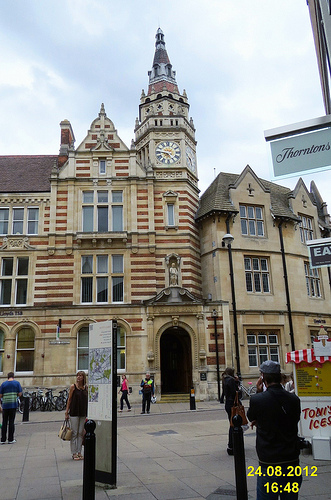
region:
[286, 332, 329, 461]
Red and white ice cream stand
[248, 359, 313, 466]
Man talking on cell phone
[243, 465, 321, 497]
Yellow time and date stamp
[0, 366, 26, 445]
Man wearing blue and green shirt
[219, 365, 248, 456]
Woman carry brown purse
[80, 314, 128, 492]
Map displayed on sidewalk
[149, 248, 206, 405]
Statue over arched doorway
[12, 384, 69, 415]
Bicycle parked near building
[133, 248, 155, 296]
Brown and tan bricks on building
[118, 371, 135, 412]
Women wearing a pink shirt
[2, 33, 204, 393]
a very tall striped building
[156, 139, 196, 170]
the two clocks on the bottom of the tower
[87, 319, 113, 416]
the sign giving directions around town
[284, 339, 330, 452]
a kiosk selling assorted ices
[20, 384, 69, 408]
a line of bikes outside the building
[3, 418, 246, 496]
part of the sidewalk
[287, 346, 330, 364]
the top of the kiosk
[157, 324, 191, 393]
the tall doorway for the building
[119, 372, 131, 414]
a woman walking down the street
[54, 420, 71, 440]
the purse the woman is holding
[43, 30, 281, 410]
old building with tall clock tower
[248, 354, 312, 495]
man talking on cell phone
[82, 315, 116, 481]
map with explanations for tourists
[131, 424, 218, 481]
large grey stones make up the street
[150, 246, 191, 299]
statue standing above an entrance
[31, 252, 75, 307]
red and beige stripes on the building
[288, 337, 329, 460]
cart selling ice cream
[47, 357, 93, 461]
woman with grey pants looks confused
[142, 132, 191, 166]
clock on the tower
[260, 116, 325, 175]
sign advertising Thornton's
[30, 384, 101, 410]
Bicycles parked on the sidewalk.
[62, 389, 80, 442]
a lady carrying a handbag.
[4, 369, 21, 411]
The shirt has stripes in the middle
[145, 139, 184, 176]
the building has a clock on top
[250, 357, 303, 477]
A man talking on a cell phone.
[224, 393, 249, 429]
The handbag is brown.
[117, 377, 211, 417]
People walking on the sidewalk.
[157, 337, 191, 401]
The door of the building.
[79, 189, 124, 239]
the building has windows.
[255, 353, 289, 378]
The man is wearing a hat.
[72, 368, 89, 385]
the head of a woman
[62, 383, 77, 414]
the arm of a woman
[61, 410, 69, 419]
the hand of a woman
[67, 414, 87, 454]
a pair of gray pants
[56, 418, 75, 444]
a tan bag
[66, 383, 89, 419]
a black tank top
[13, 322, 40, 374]
a window on the building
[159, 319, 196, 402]
a large doorway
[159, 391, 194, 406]
steps to the building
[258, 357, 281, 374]
a hat